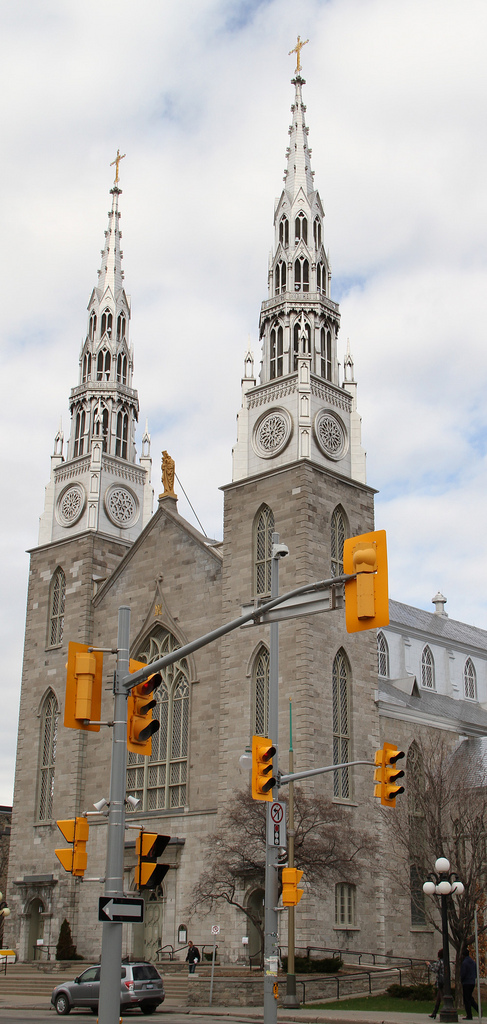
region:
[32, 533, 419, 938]
several yellow traffic lights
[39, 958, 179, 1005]
silver vehicle in front of building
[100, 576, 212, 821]
largest arched window of building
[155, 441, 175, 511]
gold statue on building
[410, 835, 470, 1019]
black post with white globe lamps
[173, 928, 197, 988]
person in black on steps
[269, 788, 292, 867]
white sign with no turn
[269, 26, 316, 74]
gold cross on right spire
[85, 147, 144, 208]
gold cross on left spire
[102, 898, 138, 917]
arrow on the sign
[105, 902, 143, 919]
the arrow is white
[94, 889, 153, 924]
the sign is black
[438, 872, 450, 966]
the light post is black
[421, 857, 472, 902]
light globes on the pole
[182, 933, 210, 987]
man on the steps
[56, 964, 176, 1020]
the car is parked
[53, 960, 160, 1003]
the car is silver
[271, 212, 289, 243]
a window on a building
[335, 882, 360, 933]
a window on a building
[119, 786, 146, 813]
a window on a building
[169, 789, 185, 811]
a window on a building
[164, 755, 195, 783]
a window on a building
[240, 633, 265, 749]
a window on a building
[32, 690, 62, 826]
a window on a building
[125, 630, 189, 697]
a window on a building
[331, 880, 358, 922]
large church has a window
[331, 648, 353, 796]
large church has a window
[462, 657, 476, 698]
large church has a window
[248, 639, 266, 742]
large church has a window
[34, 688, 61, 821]
large church has a window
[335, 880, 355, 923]
large church has a window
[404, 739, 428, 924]
large church has a window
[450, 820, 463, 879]
large church has a window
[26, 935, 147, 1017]
a view of car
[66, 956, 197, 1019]
a car on the road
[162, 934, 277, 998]
a view of iron gate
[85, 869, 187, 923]
indicator on the top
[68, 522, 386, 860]
a view of big building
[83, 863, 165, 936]
One way sign with no writing on it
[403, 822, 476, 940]
Several lights on the post near the church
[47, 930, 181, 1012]
suv driving down the street near the church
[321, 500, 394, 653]
Large traffic light above the street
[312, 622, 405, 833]
Large window on the side of the church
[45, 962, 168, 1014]
silver truck parked on street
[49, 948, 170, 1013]
silver truck parked next to steps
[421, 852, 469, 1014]
black street light with glass globes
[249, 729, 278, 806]
orange street light on pole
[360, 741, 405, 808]
orange street light on pole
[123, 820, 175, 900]
orange street light on pole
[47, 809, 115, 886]
orange street light on pole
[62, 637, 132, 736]
orange street light on pole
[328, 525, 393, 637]
orange street light on pole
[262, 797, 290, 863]
no left turn sign on pole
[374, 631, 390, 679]
glass window on building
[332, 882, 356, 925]
glass window on building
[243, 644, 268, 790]
glass window on building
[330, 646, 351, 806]
glass window on building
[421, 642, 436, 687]
glass window on building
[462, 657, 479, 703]
glass window on building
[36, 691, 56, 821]
glass window on building